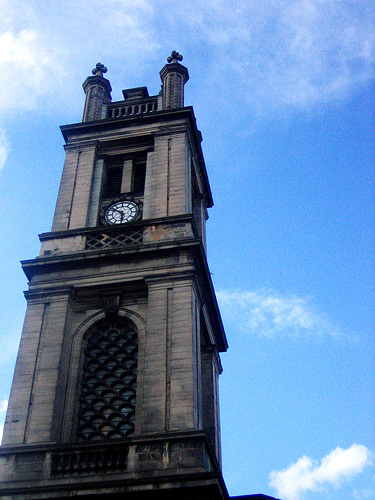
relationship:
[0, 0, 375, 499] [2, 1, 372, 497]
cloud in sky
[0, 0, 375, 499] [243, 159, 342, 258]
cloud in sky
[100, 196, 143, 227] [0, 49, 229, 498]
clock on clock tower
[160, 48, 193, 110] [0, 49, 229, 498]
post on clock tower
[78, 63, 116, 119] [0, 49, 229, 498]
post on clock tower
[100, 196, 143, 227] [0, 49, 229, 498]
clock in clock tower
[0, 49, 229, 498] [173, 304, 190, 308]
clock tower of brick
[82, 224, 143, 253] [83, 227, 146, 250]
hatch pattern of metal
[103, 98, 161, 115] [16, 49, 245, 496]
brick fence on tower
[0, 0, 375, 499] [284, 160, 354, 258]
cloud in sky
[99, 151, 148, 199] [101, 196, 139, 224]
room above clock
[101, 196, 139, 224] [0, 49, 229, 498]
clock in clock tower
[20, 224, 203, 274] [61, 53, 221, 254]
ledge on tower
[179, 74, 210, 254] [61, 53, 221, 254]
corner on tower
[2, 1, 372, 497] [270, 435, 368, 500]
sky with clouds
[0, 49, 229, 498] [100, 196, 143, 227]
clock tower with clock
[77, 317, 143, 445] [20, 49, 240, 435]
window in tower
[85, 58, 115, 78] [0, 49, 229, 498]
artwork at clock tower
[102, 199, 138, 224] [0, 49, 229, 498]
clock on clock tower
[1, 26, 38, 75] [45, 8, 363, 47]
cloud in sky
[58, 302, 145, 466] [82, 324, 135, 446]
window with scale detail